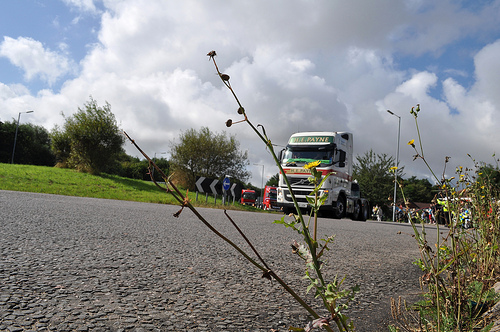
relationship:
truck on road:
[283, 135, 362, 239] [254, 216, 384, 290]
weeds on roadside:
[427, 250, 457, 299] [263, 289, 408, 327]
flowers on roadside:
[393, 279, 474, 313] [263, 289, 408, 327]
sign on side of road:
[181, 162, 241, 192] [0, 187, 475, 330]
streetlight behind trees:
[16, 101, 26, 125] [19, 126, 44, 148]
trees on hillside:
[65, 102, 144, 177] [46, 65, 156, 169]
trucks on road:
[230, 184, 276, 214] [0, 187, 475, 330]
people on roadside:
[378, 196, 444, 232] [263, 289, 408, 327]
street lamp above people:
[367, 99, 417, 246] [370, 192, 450, 232]